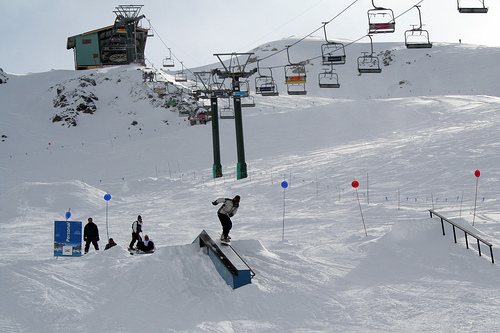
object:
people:
[82, 215, 156, 252]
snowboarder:
[214, 189, 246, 243]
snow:
[297, 124, 356, 155]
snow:
[16, 287, 59, 331]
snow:
[25, 137, 82, 160]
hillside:
[2, 32, 495, 329]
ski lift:
[126, 0, 497, 124]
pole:
[472, 167, 480, 229]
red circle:
[473, 169, 480, 177]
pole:
[366, 171, 370, 205]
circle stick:
[469, 170, 479, 227]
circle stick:
[350, 181, 369, 238]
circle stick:
[279, 179, 291, 243]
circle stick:
[103, 193, 116, 246]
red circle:
[352, 180, 359, 189]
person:
[82, 217, 98, 252]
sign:
[53, 220, 80, 257]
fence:
[426, 205, 496, 265]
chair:
[162, 57, 173, 67]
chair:
[260, 81, 280, 97]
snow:
[330, 249, 382, 269]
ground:
[293, 213, 443, 274]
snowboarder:
[193, 227, 258, 286]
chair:
[229, 75, 249, 99]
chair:
[282, 61, 308, 97]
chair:
[364, 2, 395, 42]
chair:
[404, 22, 432, 50]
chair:
[158, 53, 174, 70]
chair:
[316, 67, 341, 90]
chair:
[354, 52, 381, 76]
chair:
[254, 72, 276, 92]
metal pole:
[228, 94, 249, 181]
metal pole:
[207, 97, 224, 179]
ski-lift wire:
[261, 2, 423, 73]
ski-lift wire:
[140, 11, 195, 79]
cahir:
[317, 39, 349, 66]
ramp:
[195, 224, 253, 291]